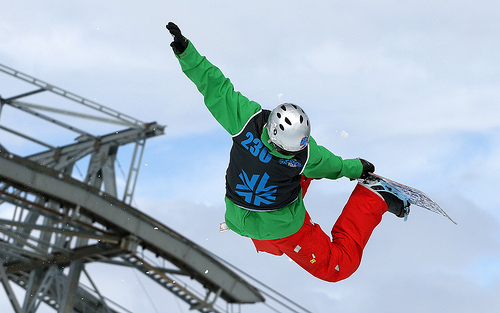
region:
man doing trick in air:
[136, 19, 458, 303]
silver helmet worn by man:
[260, 94, 298, 149]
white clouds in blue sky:
[47, 15, 101, 50]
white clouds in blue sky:
[335, 51, 382, 92]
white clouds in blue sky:
[384, 76, 426, 116]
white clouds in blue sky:
[392, 213, 430, 259]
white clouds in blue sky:
[358, 27, 430, 112]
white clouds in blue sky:
[97, 36, 131, 89]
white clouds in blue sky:
[234, 15, 267, 45]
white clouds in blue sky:
[153, 142, 195, 190]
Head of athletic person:
[262, 100, 312, 165]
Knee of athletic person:
[307, 242, 357, 277]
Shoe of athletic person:
[373, 183, 413, 223]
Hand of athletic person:
[350, 152, 375, 177]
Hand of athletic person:
[149, 21, 191, 51]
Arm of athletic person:
[182, 51, 249, 130]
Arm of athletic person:
[307, 148, 364, 180]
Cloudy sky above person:
[55, 23, 130, 66]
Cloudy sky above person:
[210, 29, 332, 59]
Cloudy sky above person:
[415, 250, 473, 287]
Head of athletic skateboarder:
[260, 100, 315, 161]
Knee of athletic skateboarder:
[305, 255, 357, 276]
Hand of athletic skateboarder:
[347, 155, 373, 175]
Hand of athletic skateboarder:
[152, 20, 184, 50]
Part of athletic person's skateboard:
[375, 170, 462, 230]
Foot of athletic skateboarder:
[360, 175, 410, 220]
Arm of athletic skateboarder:
[180, 45, 255, 125]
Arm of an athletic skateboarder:
[300, 145, 355, 180]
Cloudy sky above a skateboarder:
[65, 30, 131, 80]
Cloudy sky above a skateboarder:
[305, 46, 400, 106]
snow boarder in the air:
[145, 13, 445, 272]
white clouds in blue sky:
[35, 25, 93, 69]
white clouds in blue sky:
[302, 34, 350, 89]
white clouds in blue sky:
[350, 61, 409, 127]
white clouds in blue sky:
[420, 268, 471, 309]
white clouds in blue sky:
[154, 161, 224, 218]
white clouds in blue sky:
[332, 32, 402, 119]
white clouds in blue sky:
[396, 54, 464, 146]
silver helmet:
[265, 93, 311, 160]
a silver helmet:
[262, 96, 314, 153]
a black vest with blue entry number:
[220, 107, 309, 211]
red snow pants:
[256, 178, 386, 281]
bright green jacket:
[178, 35, 362, 235]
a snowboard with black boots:
[365, 158, 455, 225]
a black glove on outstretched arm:
[166, 19, 183, 56]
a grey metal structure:
[0, 62, 242, 312]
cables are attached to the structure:
[203, 244, 302, 311]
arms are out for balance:
[160, 4, 398, 181]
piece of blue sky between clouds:
[56, 122, 242, 175]